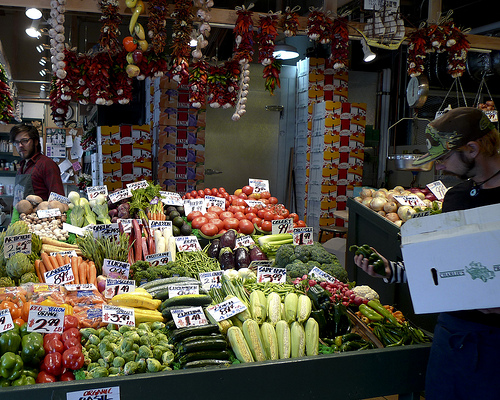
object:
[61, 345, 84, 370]
peppers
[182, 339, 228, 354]
cucumbers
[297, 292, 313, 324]
corn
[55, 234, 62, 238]
onions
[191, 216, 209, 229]
tomatoes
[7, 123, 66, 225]
man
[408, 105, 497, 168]
hat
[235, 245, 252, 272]
eggplant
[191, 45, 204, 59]
garlic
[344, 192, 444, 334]
box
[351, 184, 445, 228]
produce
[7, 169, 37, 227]
apron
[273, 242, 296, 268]
brocolee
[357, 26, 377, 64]
lights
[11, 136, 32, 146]
glasses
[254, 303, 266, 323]
ear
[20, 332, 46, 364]
peppers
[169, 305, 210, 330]
sign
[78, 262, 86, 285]
carrots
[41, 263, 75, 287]
sign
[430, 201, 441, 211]
artichokes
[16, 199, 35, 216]
mushrooms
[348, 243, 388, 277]
peppers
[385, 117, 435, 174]
basket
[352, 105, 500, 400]
man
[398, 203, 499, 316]
box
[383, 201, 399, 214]
vegetables